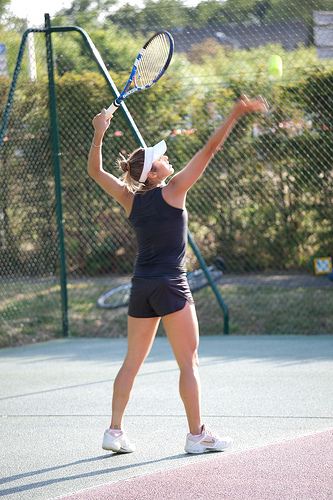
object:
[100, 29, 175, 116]
tennis racket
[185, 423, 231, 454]
shoe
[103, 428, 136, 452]
shoe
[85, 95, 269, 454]
female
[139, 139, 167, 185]
visor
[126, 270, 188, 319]
skirt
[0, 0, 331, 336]
fencing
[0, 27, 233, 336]
poles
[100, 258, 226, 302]
bicycle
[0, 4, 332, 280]
trees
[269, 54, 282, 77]
tennis ball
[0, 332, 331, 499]
tennis court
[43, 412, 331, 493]
line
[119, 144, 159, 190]
hair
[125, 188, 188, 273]
tank top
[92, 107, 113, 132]
hand